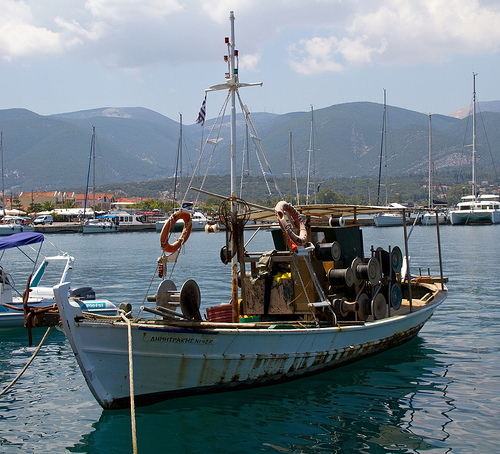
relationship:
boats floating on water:
[1, 69, 500, 453] [0, 224, 500, 452]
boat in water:
[449, 73, 500, 228] [0, 224, 500, 452]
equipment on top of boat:
[224, 202, 404, 327] [54, 10, 448, 412]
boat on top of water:
[54, 10, 448, 412] [0, 224, 500, 452]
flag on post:
[194, 92, 212, 121] [199, 11, 264, 323]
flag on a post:
[194, 92, 212, 121] [199, 11, 264, 323]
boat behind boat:
[449, 73, 500, 225] [54, 10, 448, 412]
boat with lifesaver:
[54, 10, 448, 412] [157, 211, 193, 253]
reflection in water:
[71, 333, 450, 454] [0, 224, 500, 452]